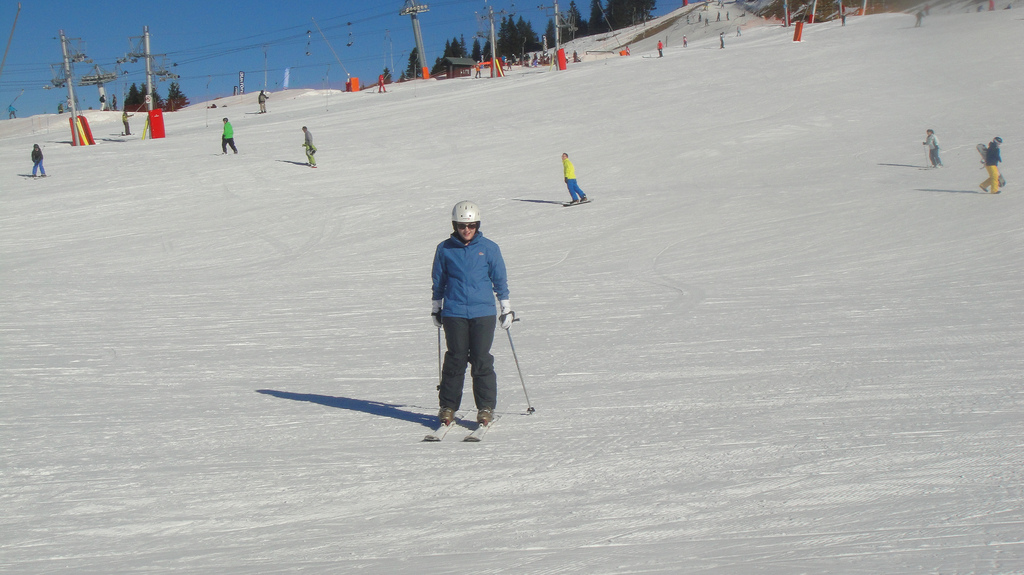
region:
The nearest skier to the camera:
[413, 199, 559, 455]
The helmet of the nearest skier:
[450, 197, 480, 227]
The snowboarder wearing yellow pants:
[977, 127, 1015, 198]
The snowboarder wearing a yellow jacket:
[547, 139, 605, 213]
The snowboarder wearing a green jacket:
[216, 113, 245, 158]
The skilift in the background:
[5, 4, 572, 113]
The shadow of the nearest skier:
[257, 383, 442, 437]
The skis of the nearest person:
[424, 415, 507, 447]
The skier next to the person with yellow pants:
[917, 127, 957, 175]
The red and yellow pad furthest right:
[57, 105, 99, 150]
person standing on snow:
[27, 139, 50, 181]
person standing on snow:
[114, 100, 134, 138]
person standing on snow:
[217, 114, 238, 159]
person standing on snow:
[433, 202, 520, 430]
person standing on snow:
[299, 122, 320, 171]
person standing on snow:
[561, 151, 584, 207]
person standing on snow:
[921, 123, 946, 168]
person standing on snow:
[977, 136, 1011, 194]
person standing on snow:
[374, 67, 388, 94]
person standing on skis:
[422, 198, 514, 448]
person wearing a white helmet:
[421, 200, 516, 447]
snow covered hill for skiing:
[5, 8, 1023, 571]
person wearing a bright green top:
[216, 112, 242, 155]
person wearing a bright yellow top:
[555, 150, 593, 208]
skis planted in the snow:
[418, 406, 501, 448]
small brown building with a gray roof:
[417, 46, 482, 84]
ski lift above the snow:
[3, 1, 883, 125]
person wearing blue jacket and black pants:
[418, 198, 520, 445]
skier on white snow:
[399, 171, 539, 444]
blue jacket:
[426, 236, 513, 335]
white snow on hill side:
[53, 193, 104, 232]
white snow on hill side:
[657, 323, 686, 363]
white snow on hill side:
[291, 496, 327, 531]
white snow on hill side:
[205, 297, 275, 373]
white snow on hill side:
[139, 281, 198, 355]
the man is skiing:
[414, 200, 523, 431]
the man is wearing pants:
[432, 322, 505, 424]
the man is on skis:
[416, 408, 515, 446]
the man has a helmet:
[446, 205, 478, 232]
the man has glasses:
[451, 220, 481, 230]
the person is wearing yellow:
[561, 161, 580, 180]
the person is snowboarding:
[558, 148, 587, 209]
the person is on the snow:
[420, 195, 545, 449]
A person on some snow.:
[429, 204, 510, 420]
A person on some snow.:
[555, 147, 585, 202]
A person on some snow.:
[305, 122, 321, 165]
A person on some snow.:
[259, 83, 272, 109]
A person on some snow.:
[122, 109, 136, 135]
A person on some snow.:
[34, 138, 53, 173]